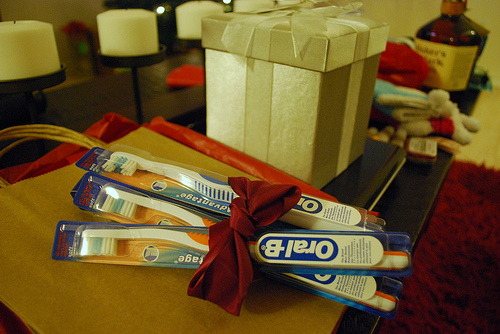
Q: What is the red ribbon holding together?
A: Toothbrushes.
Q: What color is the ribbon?
A: Red.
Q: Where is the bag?
A: Under the toothbrushes.